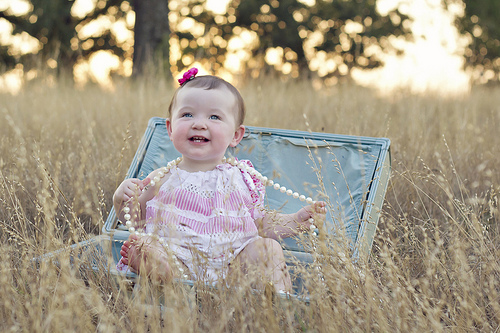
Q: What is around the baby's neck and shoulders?
A: A bead necklace.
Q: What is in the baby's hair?
A: A bow.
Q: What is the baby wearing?
A: A dress.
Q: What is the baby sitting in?
A: Suitcase.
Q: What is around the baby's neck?
A: String of pearls.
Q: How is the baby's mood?
A: Happy.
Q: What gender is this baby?
A: Female.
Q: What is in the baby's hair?
A: A pink flower.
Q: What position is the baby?
A: Sitting down.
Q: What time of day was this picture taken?
A: During daylight.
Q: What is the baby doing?
A: Smiling.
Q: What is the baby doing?
A: Showing her teeth.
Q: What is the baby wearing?
A: Pink clothing.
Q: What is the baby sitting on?
A: A suitcase.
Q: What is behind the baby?
A: Trees.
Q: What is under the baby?
A: Blue Suitcase.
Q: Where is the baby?
A: In a field.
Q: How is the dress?
A: Pink and white.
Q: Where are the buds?
A: Top of straw.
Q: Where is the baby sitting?
A: Grass.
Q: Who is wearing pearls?
A: Baby.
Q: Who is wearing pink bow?
A: Baby.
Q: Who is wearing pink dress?
A: Baby.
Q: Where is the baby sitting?
A: Suitcase.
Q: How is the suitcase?
A: Blue.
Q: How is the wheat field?
A: High.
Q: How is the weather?
A: Sunny.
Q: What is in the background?
A: Trees.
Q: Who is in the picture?
A: A baby girl.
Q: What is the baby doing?
A: Sitting in a field.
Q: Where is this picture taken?
A: A field.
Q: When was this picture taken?
A: Daytime.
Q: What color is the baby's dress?
A: Pink.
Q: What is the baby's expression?
A: She is smiling.